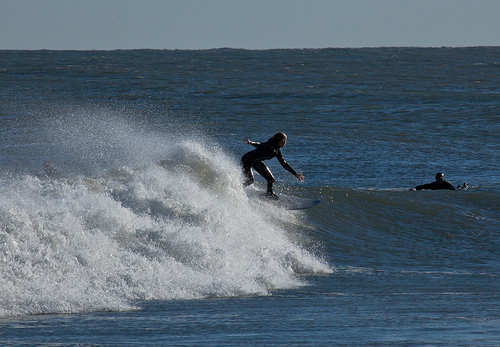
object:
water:
[0, 48, 499, 347]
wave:
[323, 187, 399, 267]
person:
[241, 131, 305, 200]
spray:
[19, 106, 167, 180]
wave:
[57, 302, 310, 346]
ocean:
[0, 45, 499, 345]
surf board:
[244, 186, 321, 211]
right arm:
[276, 151, 294, 174]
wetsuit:
[240, 142, 297, 193]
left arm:
[250, 142, 265, 146]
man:
[409, 172, 456, 191]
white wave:
[0, 238, 239, 310]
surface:
[221, 303, 445, 330]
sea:
[0, 48, 499, 346]